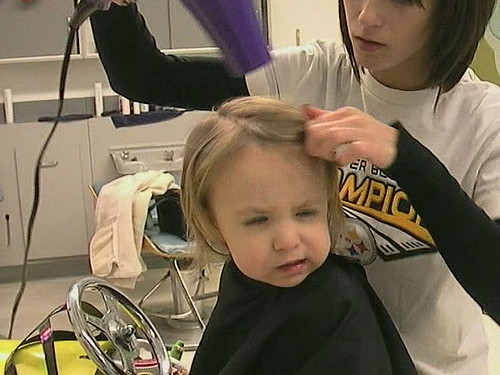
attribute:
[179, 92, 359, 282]
hair — styled, drying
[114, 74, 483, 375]
girl — little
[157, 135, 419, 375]
client — young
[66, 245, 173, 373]
wheel — silver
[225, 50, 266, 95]
hair dryer — purple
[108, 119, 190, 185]
sink — white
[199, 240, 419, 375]
cape — black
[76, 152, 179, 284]
towel — white, draped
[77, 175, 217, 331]
chair — black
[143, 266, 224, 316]
legs — metal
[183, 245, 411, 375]
towel — black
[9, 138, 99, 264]
door — white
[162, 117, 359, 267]
hair — blonde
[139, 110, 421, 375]
girl — small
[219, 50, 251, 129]
hair dryer — bright, purple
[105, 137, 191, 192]
sink — white, porcelain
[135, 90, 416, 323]
girl — wearing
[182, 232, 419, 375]
cape — black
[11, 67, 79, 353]
cord — black, electrical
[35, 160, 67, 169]
handle — silver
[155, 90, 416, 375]
girl — little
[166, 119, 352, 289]
hair — short, brown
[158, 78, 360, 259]
hair — blonde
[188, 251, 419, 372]
cape — black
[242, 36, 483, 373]
shirt — white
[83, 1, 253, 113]
shirt — black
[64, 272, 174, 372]
wheel — silver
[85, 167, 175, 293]
towels — white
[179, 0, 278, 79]
hair dryer — purple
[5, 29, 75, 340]
cord — black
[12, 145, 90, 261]
drawer — white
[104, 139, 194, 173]
sink — white